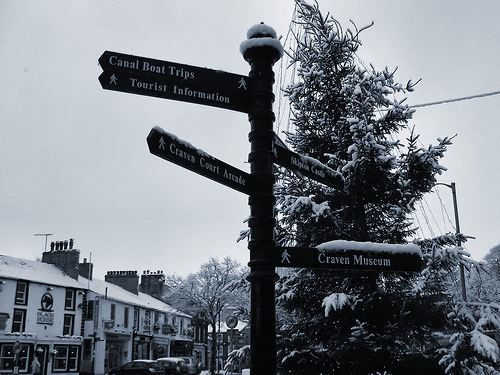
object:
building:
[84, 267, 143, 372]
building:
[146, 282, 205, 372]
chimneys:
[39, 237, 167, 299]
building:
[0, 280, 200, 370]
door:
[32, 343, 49, 373]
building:
[19, 256, 191, 356]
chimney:
[41, 237, 93, 280]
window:
[13, 280, 30, 305]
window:
[7, 308, 27, 335]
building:
[3, 237, 194, 371]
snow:
[444, 245, 471, 257]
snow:
[347, 145, 357, 168]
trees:
[188, 257, 237, 369]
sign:
[273, 245, 426, 274]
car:
[115, 357, 170, 374]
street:
[123, 360, 259, 373]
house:
[2, 234, 204, 374]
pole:
[239, 18, 286, 373]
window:
[64, 288, 78, 312]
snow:
[315, 238, 423, 253]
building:
[1, 237, 86, 373]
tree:
[248, 0, 473, 362]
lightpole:
[419, 183, 481, 303]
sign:
[95, 49, 243, 116]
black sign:
[36, 292, 57, 331]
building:
[1, 241, 93, 367]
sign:
[271, 140, 346, 190]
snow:
[260, 1, 494, 370]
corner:
[0, 2, 499, 375]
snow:
[160, 2, 497, 371]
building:
[1, 253, 102, 373]